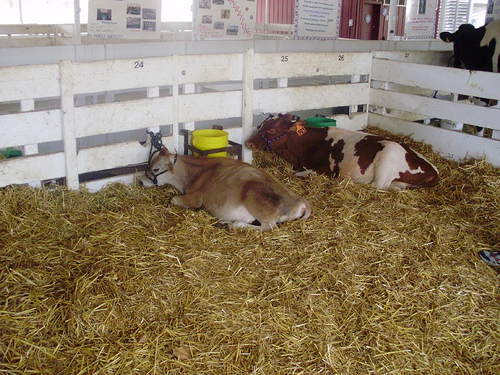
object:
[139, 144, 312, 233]
cow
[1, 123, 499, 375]
hay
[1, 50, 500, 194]
fence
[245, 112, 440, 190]
cow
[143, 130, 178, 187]
harness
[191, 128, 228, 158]
bucket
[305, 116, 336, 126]
bucket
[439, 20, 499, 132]
cow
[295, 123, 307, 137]
tag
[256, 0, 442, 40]
wall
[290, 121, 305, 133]
cow's ear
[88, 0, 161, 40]
poster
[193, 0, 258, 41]
pictures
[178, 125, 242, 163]
frame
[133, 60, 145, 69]
24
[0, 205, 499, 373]
ground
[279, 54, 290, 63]
numbers